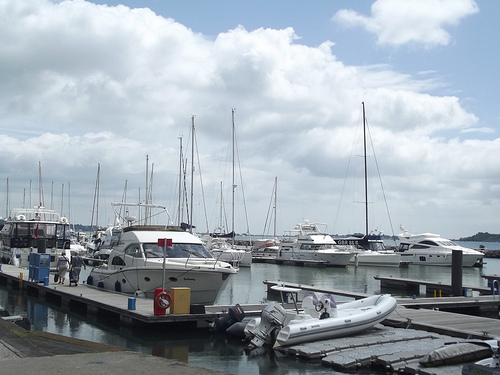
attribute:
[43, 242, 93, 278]
people — walking, holding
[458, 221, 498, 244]
hill — large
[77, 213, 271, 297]
boats — beautiful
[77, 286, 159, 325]
docks — wooden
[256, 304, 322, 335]
boat — parked, smaller, small, metal, raised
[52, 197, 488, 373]
harbor — full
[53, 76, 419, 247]
sky — blue, here, filled, cloudy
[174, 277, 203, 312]
box — red, yellow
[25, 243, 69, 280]
boxes — blue, postal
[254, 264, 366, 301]
water — calm, still, reflecting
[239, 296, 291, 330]
engine — big, small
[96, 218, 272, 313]
yatcht — docked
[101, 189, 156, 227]
sail — down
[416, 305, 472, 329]
dock — made, wooden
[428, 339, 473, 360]
bag — black, body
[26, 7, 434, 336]
photo — daytime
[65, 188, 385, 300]
yatchts — white, various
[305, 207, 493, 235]
shoreline — distant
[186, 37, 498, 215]
clouds — white, big, full